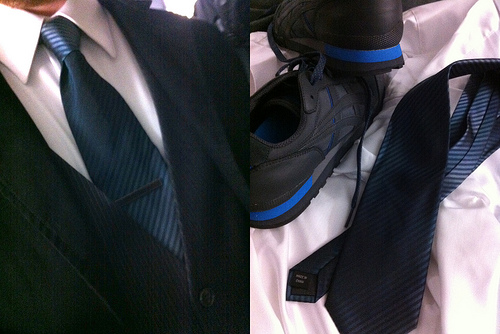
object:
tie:
[35, 15, 186, 265]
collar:
[1, 1, 117, 83]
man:
[0, 2, 248, 334]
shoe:
[266, 1, 406, 78]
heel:
[332, 48, 405, 75]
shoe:
[252, 66, 391, 230]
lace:
[343, 75, 376, 229]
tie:
[284, 58, 500, 333]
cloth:
[251, 0, 500, 334]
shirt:
[1, 0, 166, 190]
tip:
[283, 287, 304, 304]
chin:
[7, 0, 68, 10]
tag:
[288, 271, 309, 290]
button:
[199, 288, 217, 308]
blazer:
[0, 7, 250, 333]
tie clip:
[114, 180, 163, 209]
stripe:
[325, 43, 402, 62]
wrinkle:
[1, 65, 90, 177]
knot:
[40, 16, 79, 57]